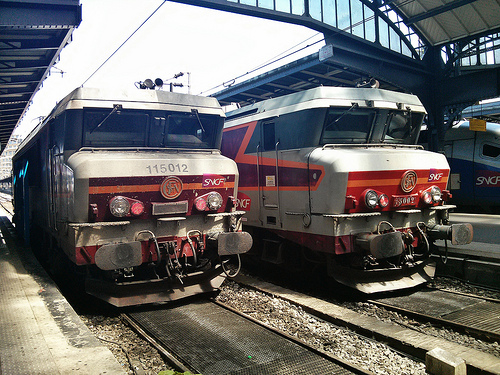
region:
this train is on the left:
[11, 75, 253, 309]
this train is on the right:
[225, 78, 474, 297]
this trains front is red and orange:
[13, 77, 253, 311]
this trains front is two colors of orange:
[226, 75, 474, 296]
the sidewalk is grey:
[2, 216, 131, 372]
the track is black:
[123, 288, 372, 374]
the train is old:
[11, 75, 254, 312]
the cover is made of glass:
[180, 0, 499, 67]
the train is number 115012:
[12, 78, 254, 313]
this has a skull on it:
[112, 242, 138, 269]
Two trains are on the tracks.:
[26, 55, 452, 310]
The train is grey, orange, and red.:
[10, 80, 255, 325]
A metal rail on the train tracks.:
[215, 295, 375, 370]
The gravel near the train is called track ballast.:
[215, 272, 430, 369]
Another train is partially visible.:
[451, 95, 497, 202]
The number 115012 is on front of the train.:
[142, 157, 189, 174]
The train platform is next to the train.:
[0, 226, 133, 371]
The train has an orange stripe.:
[87, 172, 238, 192]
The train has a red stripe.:
[345, 170, 455, 185]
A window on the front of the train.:
[318, 100, 383, 148]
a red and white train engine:
[11, 86, 251, 313]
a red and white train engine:
[215, 86, 474, 296]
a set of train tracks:
[119, 296, 371, 373]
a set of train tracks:
[356, 283, 498, 341]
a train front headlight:
[358, 185, 378, 209]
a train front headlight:
[428, 185, 439, 200]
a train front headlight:
[206, 193, 226, 209]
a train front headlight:
[110, 197, 127, 217]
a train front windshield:
[86, 108, 213, 145]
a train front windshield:
[324, 110, 420, 145]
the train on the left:
[38, 82, 289, 353]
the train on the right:
[252, 74, 467, 326]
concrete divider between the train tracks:
[267, 266, 414, 366]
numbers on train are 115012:
[137, 157, 199, 192]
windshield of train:
[313, 99, 426, 148]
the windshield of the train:
[83, 98, 214, 159]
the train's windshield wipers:
[84, 96, 208, 146]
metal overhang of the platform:
[3, 3, 57, 233]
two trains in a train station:
[0, 0, 498, 372]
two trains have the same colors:
[21, 60, 479, 322]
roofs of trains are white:
[43, 63, 433, 118]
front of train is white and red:
[66, 79, 247, 308]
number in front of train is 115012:
[51, 74, 251, 305]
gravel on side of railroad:
[94, 265, 499, 368]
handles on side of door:
[251, 133, 290, 228]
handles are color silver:
[254, 135, 288, 234]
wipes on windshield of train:
[76, 98, 224, 155]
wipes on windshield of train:
[326, 94, 423, 140]